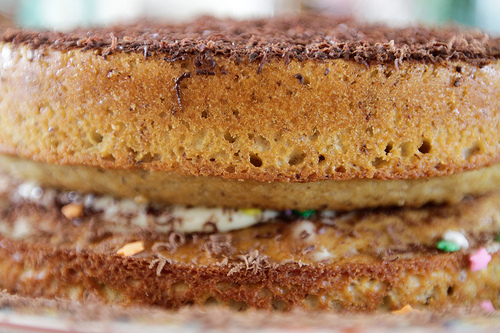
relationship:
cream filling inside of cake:
[12, 180, 280, 236] [2, 25, 497, 329]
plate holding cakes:
[4, 289, 496, 331] [4, 2, 492, 329]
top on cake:
[4, 10, 493, 64] [2, 25, 497, 329]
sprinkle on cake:
[432, 236, 467, 257] [2, 25, 497, 329]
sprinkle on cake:
[469, 254, 488, 271] [2, 25, 497, 329]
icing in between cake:
[6, 179, 277, 244] [1, 194, 498, 324]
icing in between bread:
[6, 179, 277, 244] [0, 25, 495, 216]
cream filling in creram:
[17, 179, 274, 243] [3, 23, 500, 330]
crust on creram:
[37, 51, 219, 140] [3, 23, 500, 330]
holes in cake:
[6, 241, 494, 318] [2, 25, 497, 329]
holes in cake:
[3, 82, 496, 182] [2, 25, 497, 329]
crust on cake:
[2, 11, 499, 58] [2, 25, 497, 329]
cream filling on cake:
[12, 180, 280, 236] [2, 25, 497, 329]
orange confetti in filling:
[117, 239, 144, 259] [11, 175, 292, 247]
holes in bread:
[87, 128, 165, 168] [3, 25, 495, 181]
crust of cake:
[0, 34, 500, 183] [2, 25, 497, 329]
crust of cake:
[228, 247, 468, 331] [2, 25, 497, 329]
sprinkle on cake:
[108, 232, 153, 266] [2, 25, 497, 329]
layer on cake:
[115, 63, 483, 170] [2, 25, 497, 329]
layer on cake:
[2, 191, 499, 331] [2, 25, 497, 329]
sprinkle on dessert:
[465, 247, 499, 274] [1, 11, 498, 331]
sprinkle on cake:
[430, 226, 470, 255] [125, 77, 497, 322]